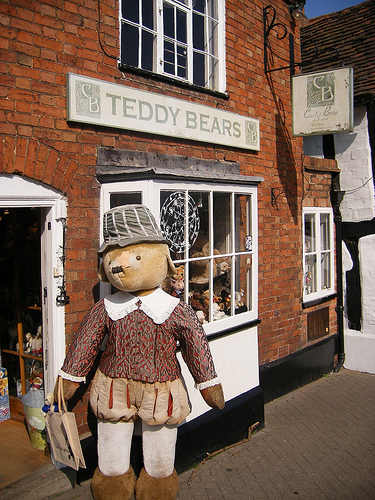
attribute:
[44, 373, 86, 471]
bag — brown, medium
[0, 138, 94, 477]
door frame —  small, short, white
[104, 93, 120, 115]
letter — green, medium, high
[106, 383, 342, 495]
sidewalk — grey, stone, lined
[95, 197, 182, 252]
hat — white, grey, striped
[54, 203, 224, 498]
teddy bear — large, tall, medium, brown, big, clothed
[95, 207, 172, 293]
teddy bear —  brown, white, large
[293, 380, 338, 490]
side walk — brick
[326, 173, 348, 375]
pipe — tall, black, thin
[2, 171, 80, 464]
door — white, rectangular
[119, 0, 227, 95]
window — white, wide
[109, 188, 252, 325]
window — wide, white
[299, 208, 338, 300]
window — white, small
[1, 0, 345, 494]
store — wide, white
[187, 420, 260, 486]
stick —  long, brown, wooden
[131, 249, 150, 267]
eye — brown, small, round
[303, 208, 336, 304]
window — square, white,  small